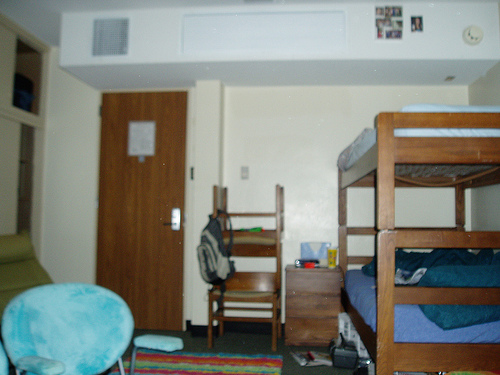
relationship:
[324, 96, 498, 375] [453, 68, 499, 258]
bunkbed side wall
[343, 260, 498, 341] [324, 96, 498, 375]
bedding on bunk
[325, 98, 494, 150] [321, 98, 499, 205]
bedding on upper bunk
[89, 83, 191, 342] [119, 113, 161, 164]
door has sign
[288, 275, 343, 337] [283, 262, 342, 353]
drawers of night table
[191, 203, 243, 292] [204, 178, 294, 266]
backpack hanging of chair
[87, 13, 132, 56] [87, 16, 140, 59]
vent of air conditioner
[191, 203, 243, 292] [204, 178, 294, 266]
backpack hangs from furniture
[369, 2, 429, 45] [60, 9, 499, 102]
pictures on wall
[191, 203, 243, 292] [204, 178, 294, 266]
back pack hanging on chair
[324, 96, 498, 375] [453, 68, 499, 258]
bunk bed against wall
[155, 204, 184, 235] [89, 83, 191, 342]
handle of door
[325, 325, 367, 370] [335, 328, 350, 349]
box has handle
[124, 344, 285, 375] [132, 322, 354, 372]
rug on floor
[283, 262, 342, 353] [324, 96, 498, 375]
dresser next bed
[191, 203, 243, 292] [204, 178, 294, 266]
back pack hangs from chair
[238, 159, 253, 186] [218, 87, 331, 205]
outlet on wall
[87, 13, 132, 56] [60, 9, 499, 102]
vent on wall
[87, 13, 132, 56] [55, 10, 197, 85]
vent mounted in soffit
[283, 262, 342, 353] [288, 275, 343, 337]
night table with 3 drawers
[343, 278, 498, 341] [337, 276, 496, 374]
bedding on bunk bed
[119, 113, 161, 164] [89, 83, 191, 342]
sign on door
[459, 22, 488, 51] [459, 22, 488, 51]
alarm of fire alarm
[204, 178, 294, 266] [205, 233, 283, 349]
chair on top of chair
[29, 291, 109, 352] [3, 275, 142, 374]
material on chair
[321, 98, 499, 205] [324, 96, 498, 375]
bunk on bunkbed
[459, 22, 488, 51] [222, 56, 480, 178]
detector on wall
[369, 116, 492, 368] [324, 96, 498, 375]
frame on bunk beds